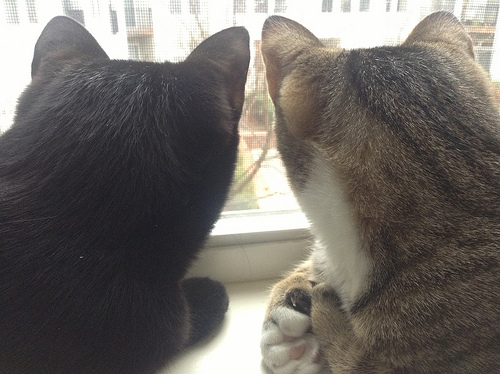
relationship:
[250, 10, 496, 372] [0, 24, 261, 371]
brown cat next to cat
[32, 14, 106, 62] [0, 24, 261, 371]
ear are part of cat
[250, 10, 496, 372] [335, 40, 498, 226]
brown cat with stripes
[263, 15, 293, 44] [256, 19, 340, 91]
hair on top ear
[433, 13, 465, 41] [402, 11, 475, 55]
hair on top ear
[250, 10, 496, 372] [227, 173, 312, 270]
brown cat looking out window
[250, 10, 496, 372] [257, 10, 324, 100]
brown cat has ear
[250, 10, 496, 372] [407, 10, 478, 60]
brown cat has ear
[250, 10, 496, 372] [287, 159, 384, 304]
brown cat has white throat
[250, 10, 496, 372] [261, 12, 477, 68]
brown cat has ears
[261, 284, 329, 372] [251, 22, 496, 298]
big paw on cat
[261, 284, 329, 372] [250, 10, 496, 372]
big paw on brown cat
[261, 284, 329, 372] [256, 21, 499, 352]
big paw on cat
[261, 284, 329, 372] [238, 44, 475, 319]
big paw on cat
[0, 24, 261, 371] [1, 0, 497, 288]
cat looking out window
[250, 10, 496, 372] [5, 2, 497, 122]
brown cat looking out window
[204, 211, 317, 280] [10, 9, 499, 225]
ledge by window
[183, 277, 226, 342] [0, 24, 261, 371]
paw of cat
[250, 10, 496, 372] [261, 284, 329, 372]
brown cat with big paw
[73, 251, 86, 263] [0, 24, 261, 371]
object on cat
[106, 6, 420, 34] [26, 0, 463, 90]
windows in back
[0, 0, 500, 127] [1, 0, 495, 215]
building outside window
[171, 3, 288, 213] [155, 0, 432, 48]
tree outside window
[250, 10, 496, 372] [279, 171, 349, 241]
brown cat has chin